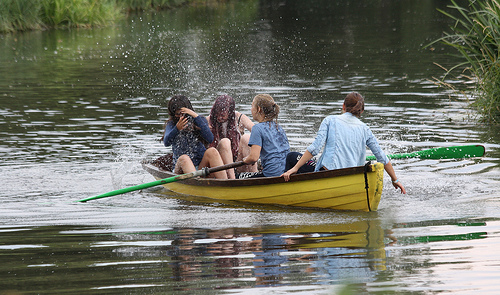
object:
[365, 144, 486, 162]
oar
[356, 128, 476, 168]
oar water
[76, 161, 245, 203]
oar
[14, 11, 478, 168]
water spray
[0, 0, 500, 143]
grass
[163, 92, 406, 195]
four people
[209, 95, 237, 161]
hair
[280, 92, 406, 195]
friend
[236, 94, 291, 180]
friend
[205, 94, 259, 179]
friend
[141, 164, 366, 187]
rail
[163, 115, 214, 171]
blue top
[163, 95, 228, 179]
female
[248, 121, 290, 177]
gray shirt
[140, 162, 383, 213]
base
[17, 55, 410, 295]
water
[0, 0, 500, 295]
air